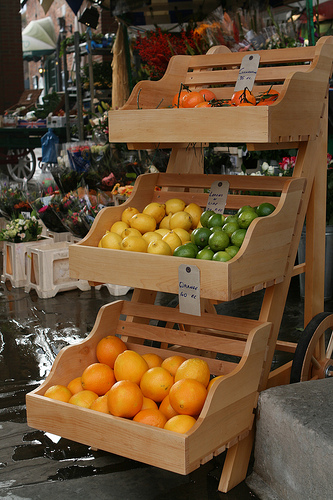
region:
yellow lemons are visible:
[112, 199, 172, 259]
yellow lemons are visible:
[96, 184, 191, 275]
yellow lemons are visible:
[112, 203, 149, 242]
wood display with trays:
[25, 111, 322, 457]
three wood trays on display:
[147, 97, 303, 448]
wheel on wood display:
[285, 309, 329, 379]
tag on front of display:
[172, 261, 203, 325]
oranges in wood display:
[89, 343, 202, 417]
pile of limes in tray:
[196, 210, 254, 263]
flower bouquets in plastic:
[33, 176, 106, 233]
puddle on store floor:
[10, 435, 95, 486]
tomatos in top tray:
[160, 73, 285, 121]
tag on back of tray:
[230, 48, 266, 99]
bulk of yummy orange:
[76, 331, 231, 498]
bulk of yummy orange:
[85, 307, 170, 429]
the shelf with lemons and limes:
[68, 162, 307, 302]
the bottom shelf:
[29, 296, 265, 455]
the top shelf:
[102, 43, 317, 148]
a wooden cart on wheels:
[36, 33, 320, 489]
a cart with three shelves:
[7, 47, 317, 477]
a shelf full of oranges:
[31, 296, 262, 454]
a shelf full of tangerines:
[109, 54, 307, 149]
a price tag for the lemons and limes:
[203, 179, 236, 216]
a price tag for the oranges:
[175, 261, 202, 318]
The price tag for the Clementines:
[230, 52, 259, 94]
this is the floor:
[14, 296, 42, 334]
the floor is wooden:
[2, 441, 21, 466]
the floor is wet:
[2, 364, 27, 373]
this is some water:
[1, 306, 42, 348]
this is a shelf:
[140, 83, 256, 460]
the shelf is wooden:
[209, 408, 227, 439]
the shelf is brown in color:
[219, 387, 243, 439]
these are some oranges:
[82, 348, 193, 408]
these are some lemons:
[127, 210, 230, 239]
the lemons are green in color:
[192, 228, 243, 245]